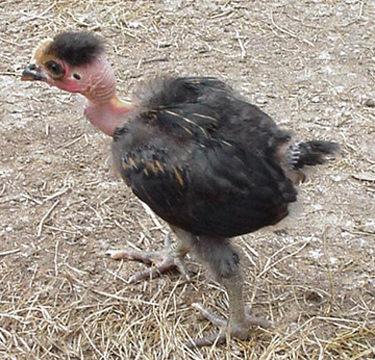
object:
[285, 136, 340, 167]
black tail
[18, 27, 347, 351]
bird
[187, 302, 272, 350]
feet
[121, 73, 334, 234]
feathers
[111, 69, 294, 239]
body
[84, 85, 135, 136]
neck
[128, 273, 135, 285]
nails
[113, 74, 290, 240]
black fur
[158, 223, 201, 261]
gray legs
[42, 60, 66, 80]
eye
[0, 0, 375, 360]
ground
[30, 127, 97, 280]
brown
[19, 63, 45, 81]
beak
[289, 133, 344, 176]
tail feathers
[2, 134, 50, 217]
dirt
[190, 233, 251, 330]
leg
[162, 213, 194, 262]
leg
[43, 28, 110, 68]
feathers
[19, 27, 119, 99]
head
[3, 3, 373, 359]
hay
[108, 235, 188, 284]
claw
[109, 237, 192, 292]
feet